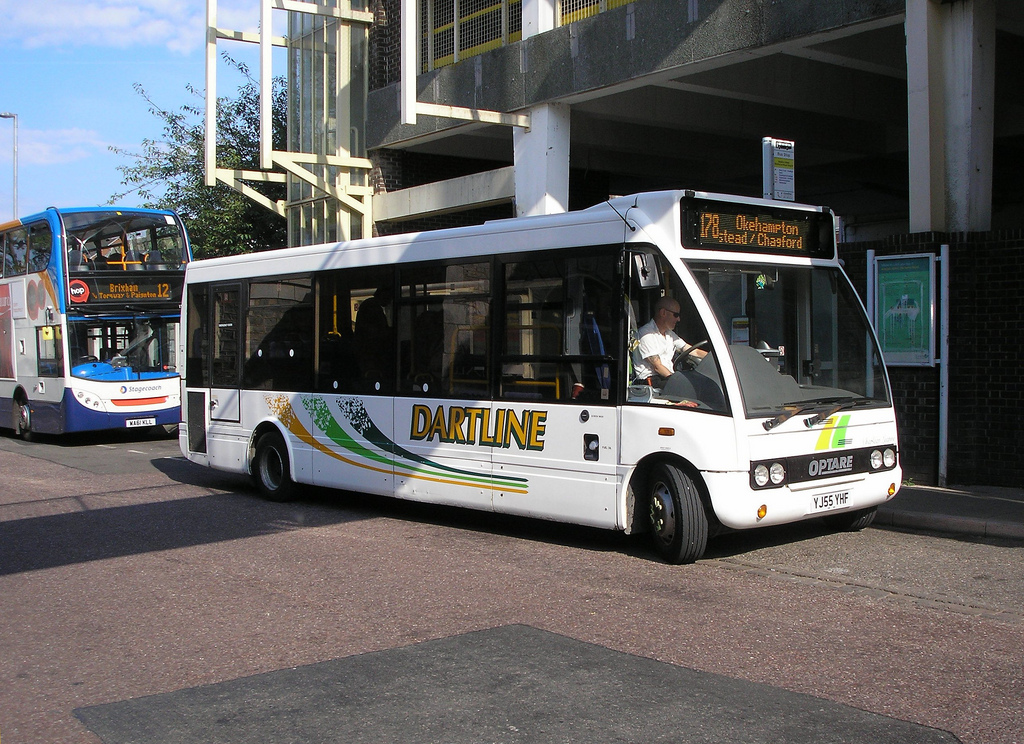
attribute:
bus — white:
[163, 179, 915, 560]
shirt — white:
[632, 319, 691, 378]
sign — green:
[870, 247, 934, 361]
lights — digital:
[692, 201, 814, 254]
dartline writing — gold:
[406, 394, 557, 456]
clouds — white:
[3, 112, 129, 174]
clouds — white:
[12, 9, 213, 68]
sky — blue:
[6, 7, 277, 203]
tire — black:
[629, 454, 715, 562]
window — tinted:
[169, 236, 636, 407]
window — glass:
[672, 243, 902, 421]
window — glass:
[613, 243, 742, 421]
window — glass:
[485, 237, 636, 402]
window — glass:
[181, 264, 255, 384]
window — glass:
[35, 315, 63, 383]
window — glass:
[242, 267, 319, 392]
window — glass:
[309, 254, 414, 394]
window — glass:
[406, 249, 510, 408]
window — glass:
[53, 206, 191, 270]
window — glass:
[57, 304, 192, 376]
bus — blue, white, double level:
[3, 200, 201, 448]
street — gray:
[1, 438, 1023, 741]